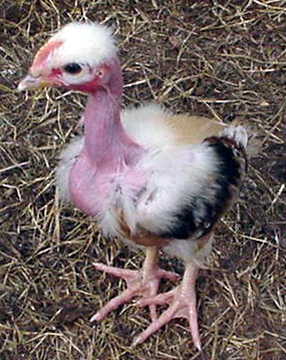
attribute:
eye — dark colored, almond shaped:
[58, 63, 80, 79]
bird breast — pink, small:
[59, 149, 145, 232]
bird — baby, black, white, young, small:
[15, 28, 264, 348]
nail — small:
[88, 310, 98, 325]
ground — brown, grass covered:
[1, 3, 283, 357]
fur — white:
[48, 107, 220, 230]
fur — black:
[161, 130, 244, 245]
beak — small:
[13, 76, 51, 96]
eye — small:
[60, 61, 82, 76]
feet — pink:
[90, 257, 203, 352]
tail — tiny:
[221, 116, 257, 164]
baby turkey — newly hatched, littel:
[19, 21, 255, 351]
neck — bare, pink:
[73, 89, 136, 161]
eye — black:
[62, 58, 80, 74]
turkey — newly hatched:
[14, 21, 253, 352]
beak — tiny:
[17, 73, 47, 93]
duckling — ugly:
[22, 22, 242, 348]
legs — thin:
[96, 232, 215, 347]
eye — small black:
[48, 53, 92, 80]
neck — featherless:
[65, 69, 149, 195]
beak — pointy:
[14, 55, 65, 110]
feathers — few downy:
[123, 106, 227, 255]